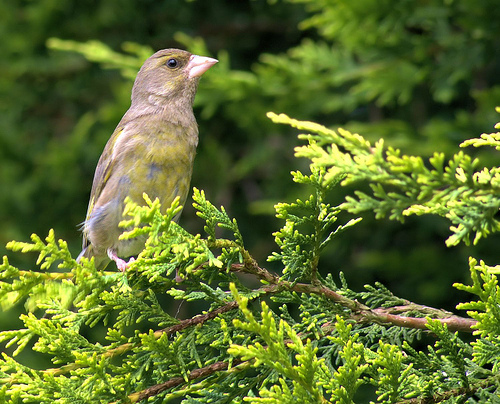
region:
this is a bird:
[90, 34, 234, 213]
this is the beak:
[184, 57, 215, 74]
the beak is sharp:
[195, 52, 220, 74]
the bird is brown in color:
[145, 87, 187, 135]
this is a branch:
[375, 294, 441, 349]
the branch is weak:
[404, 300, 472, 338]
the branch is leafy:
[231, 323, 361, 400]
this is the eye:
[165, 57, 180, 67]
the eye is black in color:
[164, 56, 180, 67]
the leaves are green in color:
[247, 318, 331, 392]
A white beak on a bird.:
[186, 51, 217, 79]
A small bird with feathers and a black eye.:
[82, 46, 219, 271]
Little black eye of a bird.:
[167, 58, 177, 68]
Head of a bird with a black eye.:
[135, 45, 197, 103]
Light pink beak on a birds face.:
[189, 53, 218, 81]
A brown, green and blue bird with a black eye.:
[81, 46, 221, 272]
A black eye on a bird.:
[166, 58, 178, 68]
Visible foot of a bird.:
[105, 246, 137, 270]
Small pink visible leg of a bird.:
[104, 246, 136, 272]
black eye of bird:
[166, 55, 179, 70]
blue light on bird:
[145, 163, 161, 183]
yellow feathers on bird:
[106, 128, 195, 210]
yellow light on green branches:
[120, 191, 187, 268]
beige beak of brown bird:
[192, 56, 218, 79]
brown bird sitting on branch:
[77, 46, 218, 268]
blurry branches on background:
[0, 0, 499, 317]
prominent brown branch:
[240, 256, 480, 350]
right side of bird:
[73, 43, 222, 278]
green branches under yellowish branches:
[151, 273, 498, 399]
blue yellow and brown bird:
[75, 43, 225, 279]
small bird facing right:
[75, 40, 224, 273]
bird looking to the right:
[77, 38, 228, 292]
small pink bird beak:
[186, 52, 221, 85]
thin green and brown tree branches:
[1, 105, 498, 402]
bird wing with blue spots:
[83, 111, 203, 263]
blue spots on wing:
[80, 155, 197, 255]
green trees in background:
[3, 1, 498, 303]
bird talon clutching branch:
[100, 243, 137, 280]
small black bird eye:
[162, 55, 182, 70]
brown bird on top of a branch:
[79, 48, 215, 272]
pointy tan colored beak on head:
[188, 54, 218, 81]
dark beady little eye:
[166, 58, 176, 70]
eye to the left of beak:
[170, 58, 178, 68]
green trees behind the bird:
[0, 0, 499, 308]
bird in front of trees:
[78, 46, 219, 261]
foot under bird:
[106, 247, 137, 274]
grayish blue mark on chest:
[146, 163, 160, 180]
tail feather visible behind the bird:
[76, 245, 111, 272]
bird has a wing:
[83, 144, 113, 251]